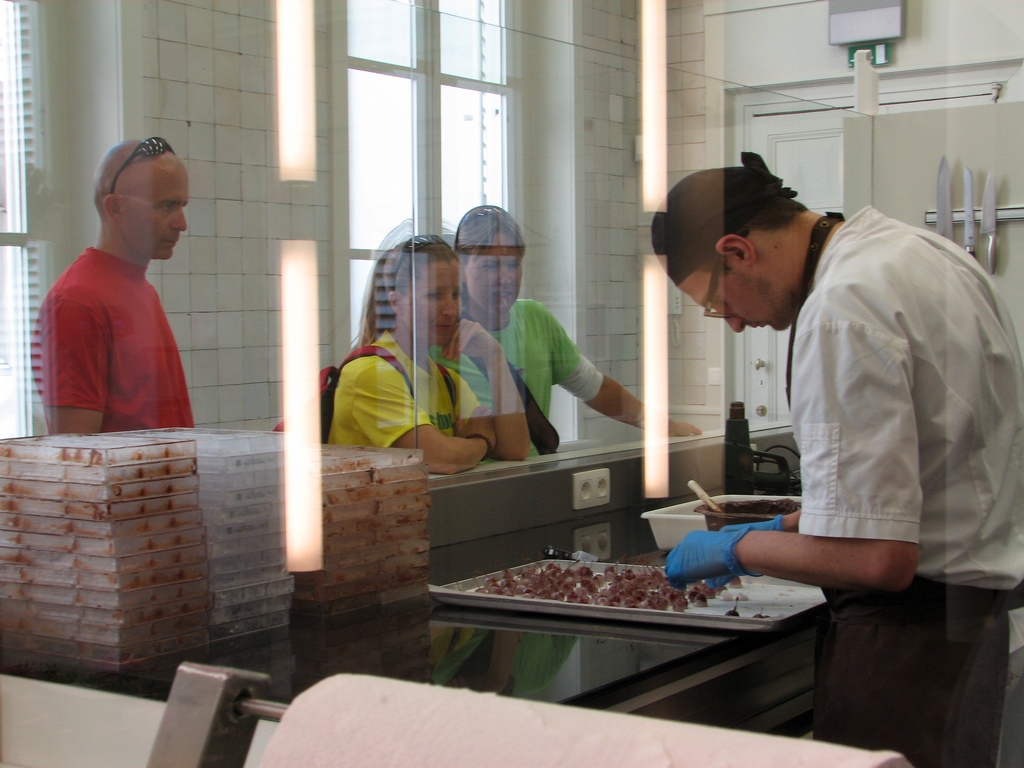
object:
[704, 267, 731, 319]
sunglasses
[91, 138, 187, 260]
head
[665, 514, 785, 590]
glove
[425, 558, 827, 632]
tray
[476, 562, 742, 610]
food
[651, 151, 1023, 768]
man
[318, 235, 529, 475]
woman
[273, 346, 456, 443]
backpack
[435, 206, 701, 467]
woman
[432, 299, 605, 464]
shirt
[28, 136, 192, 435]
man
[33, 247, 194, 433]
shirt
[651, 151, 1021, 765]
apron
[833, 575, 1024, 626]
waist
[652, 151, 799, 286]
head wrap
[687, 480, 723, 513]
handle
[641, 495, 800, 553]
bowl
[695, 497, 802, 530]
chocolate